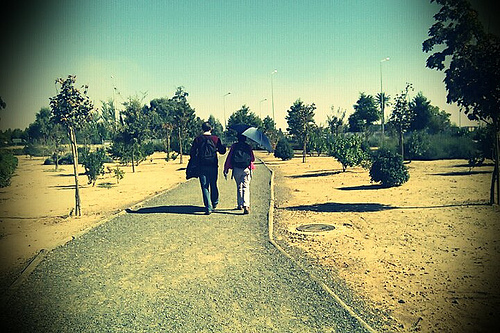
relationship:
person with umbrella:
[202, 110, 276, 209] [231, 120, 274, 156]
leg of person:
[236, 176, 264, 207] [202, 110, 276, 209]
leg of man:
[236, 176, 264, 207] [187, 121, 227, 215]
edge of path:
[254, 162, 289, 272] [124, 157, 290, 288]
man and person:
[187, 92, 237, 204] [222, 130, 256, 214]